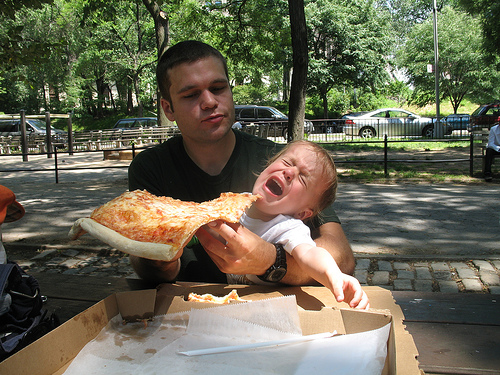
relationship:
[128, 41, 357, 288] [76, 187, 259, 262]
man holding pizza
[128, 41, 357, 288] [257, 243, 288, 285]
man wearing watch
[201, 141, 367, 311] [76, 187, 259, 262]
child eating pizza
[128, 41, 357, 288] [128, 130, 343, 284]
man wearing shirt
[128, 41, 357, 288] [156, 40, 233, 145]
man has head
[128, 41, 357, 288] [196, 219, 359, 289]
man has arm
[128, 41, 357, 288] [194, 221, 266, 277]
man has hand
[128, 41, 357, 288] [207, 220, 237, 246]
man has finger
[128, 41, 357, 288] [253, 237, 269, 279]
man has wrist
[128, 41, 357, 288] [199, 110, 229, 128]
man has mouth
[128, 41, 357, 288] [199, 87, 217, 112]
man has nose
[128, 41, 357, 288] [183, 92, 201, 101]
man has eye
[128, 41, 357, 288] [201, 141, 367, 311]
man holding boy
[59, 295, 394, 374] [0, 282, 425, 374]
paper in box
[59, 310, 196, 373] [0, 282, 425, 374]
stains on top of box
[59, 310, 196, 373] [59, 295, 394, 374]
stains on top of paper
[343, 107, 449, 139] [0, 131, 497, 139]
car on road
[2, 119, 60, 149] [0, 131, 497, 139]
car on road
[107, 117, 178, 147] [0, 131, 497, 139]
car on road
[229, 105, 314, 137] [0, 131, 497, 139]
car on road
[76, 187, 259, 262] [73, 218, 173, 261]
pizza has crust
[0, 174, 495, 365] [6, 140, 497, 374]
shadow on top of ground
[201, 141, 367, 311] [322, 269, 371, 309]
child has hand